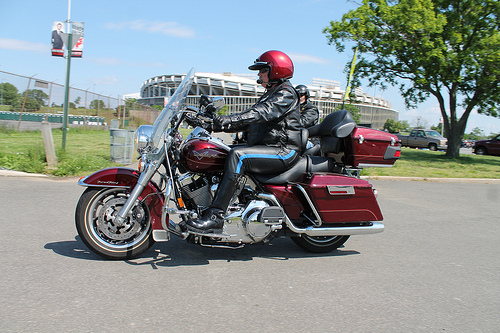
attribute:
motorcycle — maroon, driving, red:
[73, 66, 404, 264]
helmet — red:
[253, 49, 295, 83]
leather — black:
[215, 80, 304, 178]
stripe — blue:
[234, 148, 296, 175]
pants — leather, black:
[224, 143, 302, 178]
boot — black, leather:
[181, 167, 248, 236]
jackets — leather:
[227, 80, 321, 155]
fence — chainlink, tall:
[0, 68, 160, 135]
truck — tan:
[392, 127, 448, 152]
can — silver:
[108, 126, 138, 167]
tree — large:
[321, 0, 499, 161]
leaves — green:
[320, 0, 499, 122]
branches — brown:
[427, 82, 483, 130]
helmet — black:
[294, 82, 311, 101]